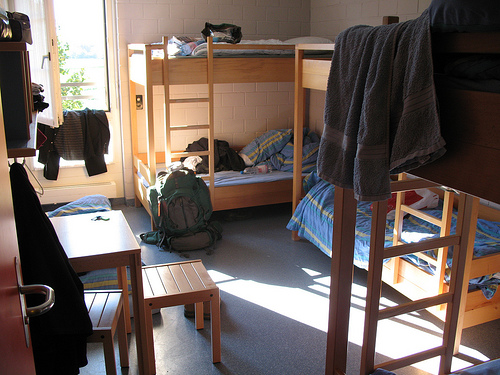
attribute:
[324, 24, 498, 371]
bed — bunk, wood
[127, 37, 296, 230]
bed — bunk, a bunk bed, wood, umade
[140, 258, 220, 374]
chair — backless, wooden, brown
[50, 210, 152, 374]
table — wood, empty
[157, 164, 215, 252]
pack — green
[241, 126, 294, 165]
case — blue, yellow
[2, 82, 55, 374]
door — open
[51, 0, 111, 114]
window — open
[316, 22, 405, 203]
towel — grey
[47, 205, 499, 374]
flooring — gray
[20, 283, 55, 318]
handle — silver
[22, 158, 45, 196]
hanger — white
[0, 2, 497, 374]
picture — messy, indoors